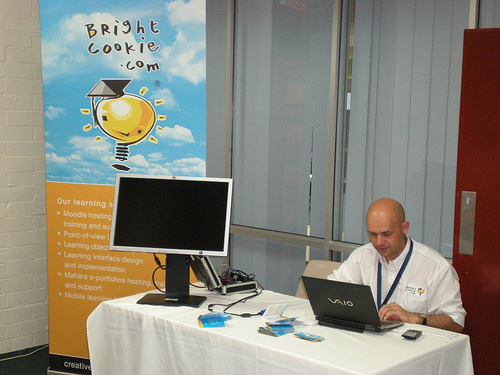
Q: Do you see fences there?
A: No, there are no fences.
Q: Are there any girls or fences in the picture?
A: No, there are no fences or girls.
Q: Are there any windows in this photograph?
A: Yes, there is a window.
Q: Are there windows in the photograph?
A: Yes, there is a window.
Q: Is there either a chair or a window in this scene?
A: Yes, there is a window.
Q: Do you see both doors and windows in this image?
A: Yes, there are both a window and a door.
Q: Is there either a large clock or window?
A: Yes, there is a large window.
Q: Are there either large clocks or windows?
A: Yes, there is a large window.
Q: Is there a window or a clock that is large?
A: Yes, the window is large.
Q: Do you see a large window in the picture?
A: Yes, there is a large window.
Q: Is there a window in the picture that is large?
A: Yes, there is a window that is large.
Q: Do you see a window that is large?
A: Yes, there is a window that is large.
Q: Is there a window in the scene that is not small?
A: Yes, there is a large window.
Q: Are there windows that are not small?
A: Yes, there is a large window.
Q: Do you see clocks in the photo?
A: No, there are no clocks.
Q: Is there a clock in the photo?
A: No, there are no clocks.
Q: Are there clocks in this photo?
A: No, there are no clocks.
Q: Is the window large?
A: Yes, the window is large.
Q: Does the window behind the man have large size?
A: Yes, the window is large.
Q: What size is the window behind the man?
A: The window is large.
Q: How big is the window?
A: The window is large.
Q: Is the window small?
A: No, the window is large.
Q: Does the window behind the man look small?
A: No, the window is large.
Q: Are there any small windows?
A: No, there is a window but it is large.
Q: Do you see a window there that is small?
A: No, there is a window but it is large.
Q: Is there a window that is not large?
A: No, there is a window but it is large.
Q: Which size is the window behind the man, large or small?
A: The window is large.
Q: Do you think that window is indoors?
A: Yes, the window is indoors.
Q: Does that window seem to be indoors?
A: Yes, the window is indoors.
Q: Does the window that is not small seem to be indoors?
A: Yes, the window is indoors.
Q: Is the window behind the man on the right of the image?
A: Yes, the window is behind the man.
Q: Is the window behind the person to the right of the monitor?
A: Yes, the window is behind the man.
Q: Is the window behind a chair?
A: No, the window is behind the man.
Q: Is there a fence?
A: No, there are no fences.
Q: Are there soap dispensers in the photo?
A: No, there are no soap dispensers.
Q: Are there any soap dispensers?
A: No, there are no soap dispensers.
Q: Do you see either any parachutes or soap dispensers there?
A: No, there are no soap dispensers or parachutes.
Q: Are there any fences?
A: No, there are no fences.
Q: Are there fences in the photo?
A: No, there are no fences.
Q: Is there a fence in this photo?
A: No, there are no fences.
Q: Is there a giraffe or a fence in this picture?
A: No, there are no fences or giraffes.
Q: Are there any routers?
A: No, there are no routers.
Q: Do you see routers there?
A: No, there are no routers.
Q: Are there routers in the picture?
A: No, there are no routers.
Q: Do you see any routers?
A: No, there are no routers.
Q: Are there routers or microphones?
A: No, there are no routers or microphones.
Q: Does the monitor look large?
A: Yes, the monitor is large.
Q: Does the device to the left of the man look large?
A: Yes, the monitor is large.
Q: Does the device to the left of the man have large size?
A: Yes, the monitor is large.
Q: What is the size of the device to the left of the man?
A: The monitor is large.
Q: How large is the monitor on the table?
A: The monitor is large.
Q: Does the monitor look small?
A: No, the monitor is large.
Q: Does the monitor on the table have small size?
A: No, the monitor is large.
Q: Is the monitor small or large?
A: The monitor is large.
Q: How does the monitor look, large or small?
A: The monitor is large.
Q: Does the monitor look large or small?
A: The monitor is large.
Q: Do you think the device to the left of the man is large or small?
A: The monitor is large.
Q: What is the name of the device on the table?
A: The device is a monitor.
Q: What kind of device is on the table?
A: The device is a monitor.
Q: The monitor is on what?
A: The monitor is on the table.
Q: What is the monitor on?
A: The monitor is on the table.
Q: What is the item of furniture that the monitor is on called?
A: The piece of furniture is a table.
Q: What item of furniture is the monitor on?
A: The monitor is on the table.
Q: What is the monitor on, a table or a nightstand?
A: The monitor is on a table.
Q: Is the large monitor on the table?
A: Yes, the monitor is on the table.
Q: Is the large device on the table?
A: Yes, the monitor is on the table.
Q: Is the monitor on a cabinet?
A: No, the monitor is on the table.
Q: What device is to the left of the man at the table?
A: The device is a monitor.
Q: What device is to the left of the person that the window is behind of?
A: The device is a monitor.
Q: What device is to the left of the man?
A: The device is a monitor.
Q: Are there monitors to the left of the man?
A: Yes, there is a monitor to the left of the man.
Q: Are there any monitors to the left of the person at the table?
A: Yes, there is a monitor to the left of the man.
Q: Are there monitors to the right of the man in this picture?
A: No, the monitor is to the left of the man.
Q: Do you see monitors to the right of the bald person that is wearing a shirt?
A: No, the monitor is to the left of the man.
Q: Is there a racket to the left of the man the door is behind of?
A: No, there is a monitor to the left of the man.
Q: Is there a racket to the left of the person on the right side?
A: No, there is a monitor to the left of the man.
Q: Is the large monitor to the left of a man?
A: Yes, the monitor is to the left of a man.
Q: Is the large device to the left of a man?
A: Yes, the monitor is to the left of a man.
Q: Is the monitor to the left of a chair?
A: No, the monitor is to the left of a man.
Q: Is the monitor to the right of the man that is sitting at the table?
A: No, the monitor is to the left of the man.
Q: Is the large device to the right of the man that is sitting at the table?
A: No, the monitor is to the left of the man.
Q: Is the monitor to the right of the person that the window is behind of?
A: No, the monitor is to the left of the man.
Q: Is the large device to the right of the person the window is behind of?
A: No, the monitor is to the left of the man.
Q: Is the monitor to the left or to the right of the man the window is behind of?
A: The monitor is to the left of the man.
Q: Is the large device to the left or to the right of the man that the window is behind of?
A: The monitor is to the left of the man.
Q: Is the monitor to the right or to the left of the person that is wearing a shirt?
A: The monitor is to the left of the man.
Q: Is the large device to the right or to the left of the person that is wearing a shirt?
A: The monitor is to the left of the man.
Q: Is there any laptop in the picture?
A: Yes, there is a laptop.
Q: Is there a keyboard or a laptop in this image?
A: Yes, there is a laptop.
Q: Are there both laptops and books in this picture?
A: No, there is a laptop but no books.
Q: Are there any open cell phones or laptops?
A: Yes, there is an open laptop.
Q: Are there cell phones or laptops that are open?
A: Yes, the laptop is open.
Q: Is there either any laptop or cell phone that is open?
A: Yes, the laptop is open.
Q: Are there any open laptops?
A: Yes, there is an open laptop.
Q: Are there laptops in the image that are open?
A: Yes, there is a laptop that is open.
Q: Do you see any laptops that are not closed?
A: Yes, there is a open laptop.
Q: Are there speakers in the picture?
A: No, there are no speakers.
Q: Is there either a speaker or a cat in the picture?
A: No, there are no speakers or cats.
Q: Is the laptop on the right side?
A: Yes, the laptop is on the right of the image.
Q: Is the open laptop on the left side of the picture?
A: No, the laptop is on the right of the image.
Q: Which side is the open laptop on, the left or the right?
A: The laptop is on the right of the image.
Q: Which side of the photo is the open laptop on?
A: The laptop is on the right of the image.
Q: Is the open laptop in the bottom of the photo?
A: Yes, the laptop is in the bottom of the image.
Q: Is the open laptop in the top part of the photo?
A: No, the laptop is in the bottom of the image.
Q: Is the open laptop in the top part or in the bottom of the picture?
A: The laptop is in the bottom of the image.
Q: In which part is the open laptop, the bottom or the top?
A: The laptop is in the bottom of the image.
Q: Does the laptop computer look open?
A: Yes, the laptop computer is open.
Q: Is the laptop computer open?
A: Yes, the laptop computer is open.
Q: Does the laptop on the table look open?
A: Yes, the laptop is open.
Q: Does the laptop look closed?
A: No, the laptop is open.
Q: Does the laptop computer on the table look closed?
A: No, the laptop is open.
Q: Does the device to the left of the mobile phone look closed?
A: No, the laptop is open.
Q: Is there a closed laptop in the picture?
A: No, there is a laptop but it is open.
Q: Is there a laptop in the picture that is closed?
A: No, there is a laptop but it is open.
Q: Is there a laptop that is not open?
A: No, there is a laptop but it is open.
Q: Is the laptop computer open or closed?
A: The laptop computer is open.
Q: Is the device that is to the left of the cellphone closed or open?
A: The laptop computer is open.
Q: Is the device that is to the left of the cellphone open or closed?
A: The laptop computer is open.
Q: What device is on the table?
A: The device is a laptop.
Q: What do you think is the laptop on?
A: The laptop is on the table.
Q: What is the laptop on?
A: The laptop is on the table.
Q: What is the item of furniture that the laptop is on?
A: The piece of furniture is a table.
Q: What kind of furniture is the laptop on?
A: The laptop is on the table.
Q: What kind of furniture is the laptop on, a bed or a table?
A: The laptop is on a table.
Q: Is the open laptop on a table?
A: Yes, the laptop is on a table.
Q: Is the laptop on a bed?
A: No, the laptop is on a table.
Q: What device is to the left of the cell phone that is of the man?
A: The device is a laptop.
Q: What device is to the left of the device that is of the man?
A: The device is a laptop.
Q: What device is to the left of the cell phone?
A: The device is a laptop.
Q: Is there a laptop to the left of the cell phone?
A: Yes, there is a laptop to the left of the cell phone.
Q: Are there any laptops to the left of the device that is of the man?
A: Yes, there is a laptop to the left of the cell phone.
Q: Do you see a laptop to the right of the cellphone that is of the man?
A: No, the laptop is to the left of the cellphone.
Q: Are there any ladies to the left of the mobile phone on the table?
A: No, there is a laptop to the left of the mobile phone.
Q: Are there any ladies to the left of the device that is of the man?
A: No, there is a laptop to the left of the mobile phone.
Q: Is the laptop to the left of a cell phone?
A: Yes, the laptop is to the left of a cell phone.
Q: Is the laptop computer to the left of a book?
A: No, the laptop computer is to the left of a cell phone.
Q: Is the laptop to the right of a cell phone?
A: No, the laptop is to the left of a cell phone.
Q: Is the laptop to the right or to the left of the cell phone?
A: The laptop is to the left of the cell phone.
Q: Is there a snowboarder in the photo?
A: No, there are no snowboarders.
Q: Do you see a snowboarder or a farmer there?
A: No, there are no snowboarders or farmers.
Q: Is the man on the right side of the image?
A: Yes, the man is on the right of the image.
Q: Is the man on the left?
A: No, the man is on the right of the image.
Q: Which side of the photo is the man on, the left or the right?
A: The man is on the right of the image.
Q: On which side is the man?
A: The man is on the right of the image.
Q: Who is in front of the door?
A: The man is in front of the door.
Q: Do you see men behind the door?
A: No, the man is in front of the door.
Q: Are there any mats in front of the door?
A: No, there is a man in front of the door.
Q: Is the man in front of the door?
A: Yes, the man is in front of the door.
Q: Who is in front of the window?
A: The man is in front of the window.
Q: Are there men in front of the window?
A: Yes, there is a man in front of the window.